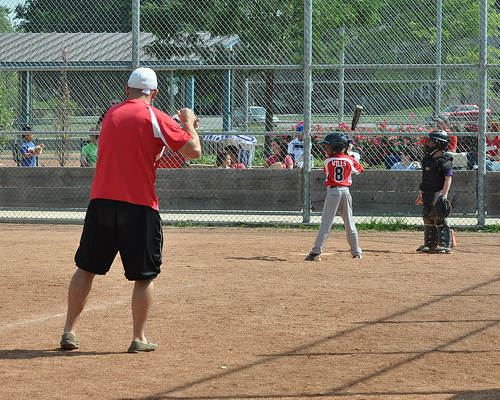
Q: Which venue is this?
A: This is a field.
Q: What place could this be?
A: It is a field.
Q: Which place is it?
A: It is a field.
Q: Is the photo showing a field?
A: Yes, it is showing a field.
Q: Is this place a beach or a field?
A: It is a field.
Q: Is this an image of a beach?
A: No, the picture is showing a field.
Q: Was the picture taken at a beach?
A: No, the picture was taken in a field.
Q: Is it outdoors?
A: Yes, it is outdoors.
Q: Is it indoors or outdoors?
A: It is outdoors.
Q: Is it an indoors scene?
A: No, it is outdoors.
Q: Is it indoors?
A: No, it is outdoors.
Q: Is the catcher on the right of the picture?
A: Yes, the catcher is on the right of the image.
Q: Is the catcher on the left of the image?
A: No, the catcher is on the right of the image.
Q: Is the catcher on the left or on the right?
A: The catcher is on the right of the image.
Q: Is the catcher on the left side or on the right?
A: The catcher is on the right of the image.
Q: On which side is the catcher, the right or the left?
A: The catcher is on the right of the image.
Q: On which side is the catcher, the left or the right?
A: The catcher is on the right of the image.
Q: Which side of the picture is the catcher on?
A: The catcher is on the right of the image.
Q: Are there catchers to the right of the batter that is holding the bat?
A: Yes, there is a catcher to the right of the batter.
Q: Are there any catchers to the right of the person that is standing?
A: Yes, there is a catcher to the right of the batter.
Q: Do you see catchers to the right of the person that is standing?
A: Yes, there is a catcher to the right of the batter.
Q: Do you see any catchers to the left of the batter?
A: No, the catcher is to the right of the batter.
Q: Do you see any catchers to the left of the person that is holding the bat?
A: No, the catcher is to the right of the batter.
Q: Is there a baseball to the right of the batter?
A: No, there is a catcher to the right of the batter.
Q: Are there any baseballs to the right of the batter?
A: No, there is a catcher to the right of the batter.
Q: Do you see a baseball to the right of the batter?
A: No, there is a catcher to the right of the batter.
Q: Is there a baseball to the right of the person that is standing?
A: No, there is a catcher to the right of the batter.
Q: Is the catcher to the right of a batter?
A: Yes, the catcher is to the right of a batter.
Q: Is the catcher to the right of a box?
A: No, the catcher is to the right of a batter.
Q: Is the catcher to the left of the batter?
A: No, the catcher is to the right of the batter.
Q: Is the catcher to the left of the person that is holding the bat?
A: No, the catcher is to the right of the batter.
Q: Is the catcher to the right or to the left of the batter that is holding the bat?
A: The catcher is to the right of the batter.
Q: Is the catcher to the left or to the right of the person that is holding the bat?
A: The catcher is to the right of the batter.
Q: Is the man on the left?
A: Yes, the man is on the left of the image.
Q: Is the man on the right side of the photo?
A: No, the man is on the left of the image.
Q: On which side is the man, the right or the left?
A: The man is on the left of the image.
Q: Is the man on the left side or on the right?
A: The man is on the left of the image.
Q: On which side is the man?
A: The man is on the left of the image.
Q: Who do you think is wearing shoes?
A: The man is wearing shoes.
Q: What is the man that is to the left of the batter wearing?
A: The man is wearing shoes.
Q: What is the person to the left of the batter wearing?
A: The man is wearing shoes.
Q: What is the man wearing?
A: The man is wearing shoes.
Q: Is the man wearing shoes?
A: Yes, the man is wearing shoes.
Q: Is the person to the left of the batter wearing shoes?
A: Yes, the man is wearing shoes.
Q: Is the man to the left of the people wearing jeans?
A: No, the man is wearing shoes.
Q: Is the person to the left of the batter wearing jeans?
A: No, the man is wearing shoes.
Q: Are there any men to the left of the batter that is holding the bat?
A: Yes, there is a man to the left of the batter.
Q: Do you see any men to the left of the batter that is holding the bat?
A: Yes, there is a man to the left of the batter.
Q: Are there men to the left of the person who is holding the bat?
A: Yes, there is a man to the left of the batter.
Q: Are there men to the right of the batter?
A: No, the man is to the left of the batter.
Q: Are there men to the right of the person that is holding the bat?
A: No, the man is to the left of the batter.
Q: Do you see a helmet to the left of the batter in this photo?
A: No, there is a man to the left of the batter.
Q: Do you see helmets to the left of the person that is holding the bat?
A: No, there is a man to the left of the batter.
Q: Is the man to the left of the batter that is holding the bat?
A: Yes, the man is to the left of the batter.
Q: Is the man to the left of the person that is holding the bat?
A: Yes, the man is to the left of the batter.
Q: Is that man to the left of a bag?
A: No, the man is to the left of the batter.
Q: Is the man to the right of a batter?
A: No, the man is to the left of a batter.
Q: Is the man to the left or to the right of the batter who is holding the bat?
A: The man is to the left of the batter.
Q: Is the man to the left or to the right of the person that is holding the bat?
A: The man is to the left of the batter.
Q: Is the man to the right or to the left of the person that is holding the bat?
A: The man is to the left of the batter.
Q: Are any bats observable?
A: Yes, there is a bat.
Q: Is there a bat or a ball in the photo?
A: Yes, there is a bat.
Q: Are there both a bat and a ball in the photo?
A: No, there is a bat but no balls.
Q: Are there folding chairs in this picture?
A: No, there are no folding chairs.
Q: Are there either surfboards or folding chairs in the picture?
A: No, there are no folding chairs or surfboards.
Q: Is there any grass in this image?
A: Yes, there is grass.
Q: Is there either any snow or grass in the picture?
A: Yes, there is grass.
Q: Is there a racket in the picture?
A: No, there are no rackets.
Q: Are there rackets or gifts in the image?
A: No, there are no rackets or gifts.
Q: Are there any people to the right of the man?
A: Yes, there are people to the right of the man.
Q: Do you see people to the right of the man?
A: Yes, there are people to the right of the man.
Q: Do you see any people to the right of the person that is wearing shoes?
A: Yes, there are people to the right of the man.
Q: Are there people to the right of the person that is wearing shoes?
A: Yes, there are people to the right of the man.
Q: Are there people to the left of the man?
A: No, the people are to the right of the man.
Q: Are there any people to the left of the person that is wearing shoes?
A: No, the people are to the right of the man.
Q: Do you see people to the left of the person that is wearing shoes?
A: No, the people are to the right of the man.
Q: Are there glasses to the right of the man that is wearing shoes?
A: No, there are people to the right of the man.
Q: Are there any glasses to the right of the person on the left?
A: No, there are people to the right of the man.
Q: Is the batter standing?
A: Yes, the batter is standing.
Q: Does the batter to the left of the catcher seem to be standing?
A: Yes, the batter is standing.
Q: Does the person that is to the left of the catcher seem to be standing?
A: Yes, the batter is standing.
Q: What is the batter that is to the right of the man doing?
A: The batter is standing.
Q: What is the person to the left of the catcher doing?
A: The batter is standing.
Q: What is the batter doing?
A: The batter is standing.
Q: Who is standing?
A: The batter is standing.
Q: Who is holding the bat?
A: The batter is holding the bat.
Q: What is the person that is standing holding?
A: The batter is holding the bat.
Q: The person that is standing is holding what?
A: The batter is holding the bat.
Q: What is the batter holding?
A: The batter is holding the bat.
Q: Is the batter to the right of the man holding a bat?
A: Yes, the batter is holding a bat.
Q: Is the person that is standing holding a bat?
A: Yes, the batter is holding a bat.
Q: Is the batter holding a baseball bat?
A: No, the batter is holding a bat.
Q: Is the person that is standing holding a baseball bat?
A: No, the batter is holding a bat.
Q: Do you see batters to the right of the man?
A: Yes, there is a batter to the right of the man.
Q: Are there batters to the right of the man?
A: Yes, there is a batter to the right of the man.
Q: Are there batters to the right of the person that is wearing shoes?
A: Yes, there is a batter to the right of the man.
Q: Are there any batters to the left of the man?
A: No, the batter is to the right of the man.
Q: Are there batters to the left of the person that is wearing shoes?
A: No, the batter is to the right of the man.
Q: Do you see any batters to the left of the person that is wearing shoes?
A: No, the batter is to the right of the man.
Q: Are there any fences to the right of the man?
A: No, there is a batter to the right of the man.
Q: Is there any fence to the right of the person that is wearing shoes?
A: No, there is a batter to the right of the man.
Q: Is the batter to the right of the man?
A: Yes, the batter is to the right of the man.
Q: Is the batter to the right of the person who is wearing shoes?
A: Yes, the batter is to the right of the man.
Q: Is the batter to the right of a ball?
A: No, the batter is to the right of the man.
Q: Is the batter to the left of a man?
A: No, the batter is to the right of a man.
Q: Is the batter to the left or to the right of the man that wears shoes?
A: The batter is to the right of the man.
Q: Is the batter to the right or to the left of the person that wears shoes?
A: The batter is to the right of the man.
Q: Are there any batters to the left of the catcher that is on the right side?
A: Yes, there is a batter to the left of the catcher.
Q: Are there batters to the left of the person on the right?
A: Yes, there is a batter to the left of the catcher.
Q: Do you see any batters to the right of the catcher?
A: No, the batter is to the left of the catcher.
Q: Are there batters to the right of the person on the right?
A: No, the batter is to the left of the catcher.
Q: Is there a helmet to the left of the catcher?
A: No, there is a batter to the left of the catcher.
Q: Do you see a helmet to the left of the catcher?
A: No, there is a batter to the left of the catcher.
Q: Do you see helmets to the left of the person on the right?
A: No, there is a batter to the left of the catcher.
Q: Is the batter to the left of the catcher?
A: Yes, the batter is to the left of the catcher.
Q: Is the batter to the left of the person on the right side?
A: Yes, the batter is to the left of the catcher.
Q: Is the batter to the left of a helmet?
A: No, the batter is to the left of the catcher.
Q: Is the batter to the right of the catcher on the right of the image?
A: No, the batter is to the left of the catcher.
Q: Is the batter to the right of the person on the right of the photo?
A: No, the batter is to the left of the catcher.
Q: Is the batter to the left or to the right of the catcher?
A: The batter is to the left of the catcher.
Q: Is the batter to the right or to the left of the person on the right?
A: The batter is to the left of the catcher.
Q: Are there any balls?
A: No, there are no balls.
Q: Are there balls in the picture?
A: No, there are no balls.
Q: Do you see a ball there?
A: No, there are no balls.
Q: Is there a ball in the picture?
A: No, there are no balls.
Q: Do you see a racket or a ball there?
A: No, there are no balls or rackets.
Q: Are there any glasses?
A: No, there are no glasses.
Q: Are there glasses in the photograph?
A: No, there are no glasses.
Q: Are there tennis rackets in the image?
A: No, there are no tennis rackets.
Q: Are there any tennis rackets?
A: No, there are no tennis rackets.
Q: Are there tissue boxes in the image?
A: No, there are no tissue boxes.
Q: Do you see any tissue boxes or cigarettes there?
A: No, there are no tissue boxes or cigarettes.